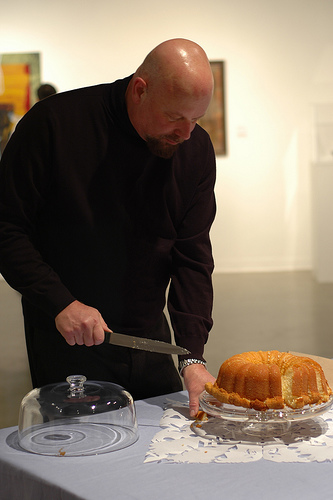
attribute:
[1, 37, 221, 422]
man — bald, standing, dressed, cutting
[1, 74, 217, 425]
clothes — black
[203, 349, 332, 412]
cake — unfrosted, sponge, vanilla, bundt, sliced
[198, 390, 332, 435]
cake stand — glass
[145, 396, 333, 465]
doily — white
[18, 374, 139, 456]
cover — glass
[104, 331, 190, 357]
knife — silver, long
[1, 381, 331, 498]
table — white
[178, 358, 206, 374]
watch — silver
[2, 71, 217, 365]
shirt — black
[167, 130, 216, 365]
sleeve — long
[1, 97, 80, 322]
sleeve — long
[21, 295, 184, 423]
pants — black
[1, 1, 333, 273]
wall — white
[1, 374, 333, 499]
table cloth — white, gray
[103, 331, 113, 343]
handle — black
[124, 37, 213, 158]
head — bald